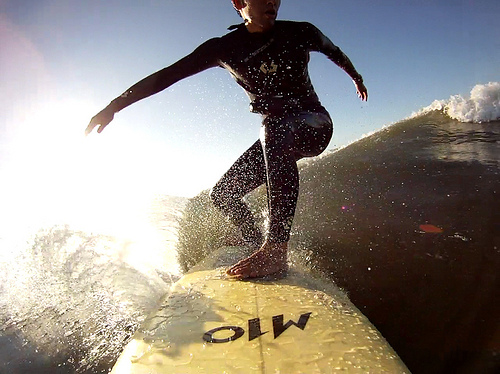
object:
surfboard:
[106, 236, 411, 374]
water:
[1, 88, 498, 374]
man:
[82, 0, 366, 283]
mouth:
[262, 11, 279, 19]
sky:
[0, 0, 500, 237]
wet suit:
[112, 20, 361, 242]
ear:
[231, 1, 245, 9]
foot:
[225, 248, 288, 277]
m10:
[199, 313, 310, 342]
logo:
[258, 61, 279, 75]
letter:
[201, 325, 244, 344]